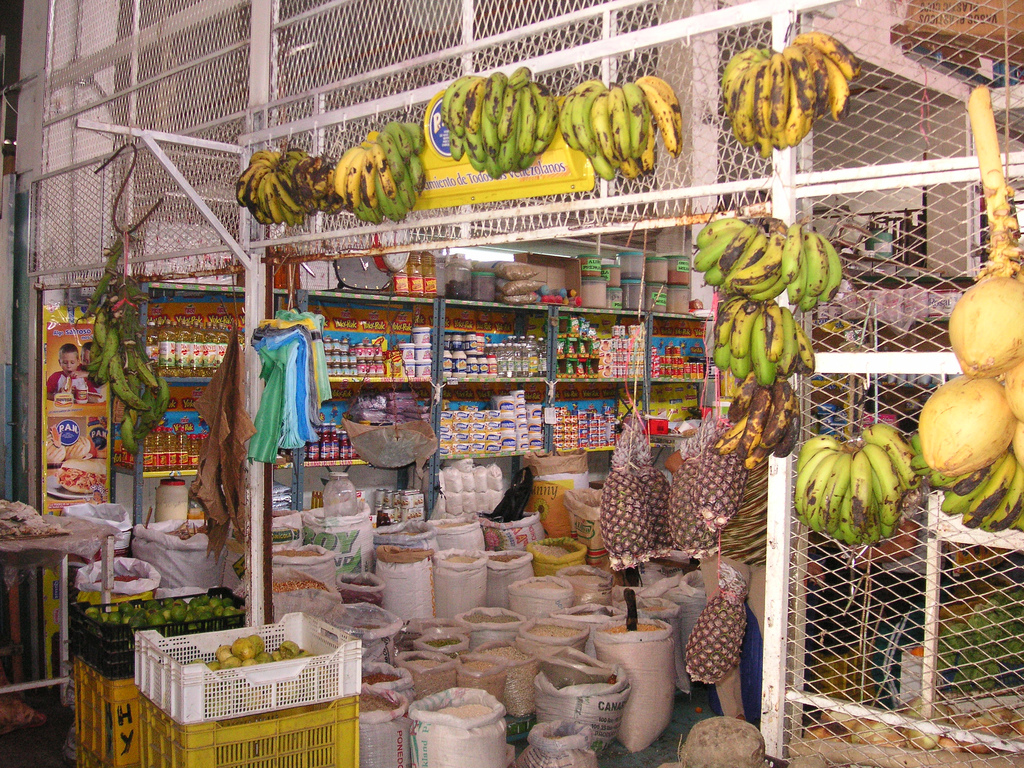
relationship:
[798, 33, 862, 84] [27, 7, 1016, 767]
banana hanging on wall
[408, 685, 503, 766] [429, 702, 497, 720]
sack has grain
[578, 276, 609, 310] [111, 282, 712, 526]
jar on top of shelf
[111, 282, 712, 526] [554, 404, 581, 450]
shelf has canned goods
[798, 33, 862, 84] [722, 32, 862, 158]
banana in banana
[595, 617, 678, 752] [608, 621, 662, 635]
sack has spice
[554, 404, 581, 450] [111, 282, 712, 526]
canned goods are on top of shelf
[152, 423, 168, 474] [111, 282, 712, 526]
bottle on top of shelf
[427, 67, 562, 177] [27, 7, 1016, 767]
bananas hanging on wall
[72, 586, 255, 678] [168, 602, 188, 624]
crate has fruit